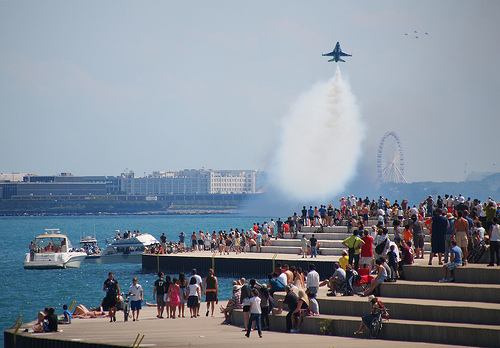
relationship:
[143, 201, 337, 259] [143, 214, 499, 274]
people on stairs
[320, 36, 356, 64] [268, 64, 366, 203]
jet with trail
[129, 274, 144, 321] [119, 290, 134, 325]
man with bicycle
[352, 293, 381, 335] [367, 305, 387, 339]
woman with bike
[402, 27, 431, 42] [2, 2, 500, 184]
jets in sky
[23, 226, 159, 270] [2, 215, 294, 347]
boats in water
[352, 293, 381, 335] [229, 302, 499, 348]
woman sitting on stair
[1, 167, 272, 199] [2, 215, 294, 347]
buildings by water